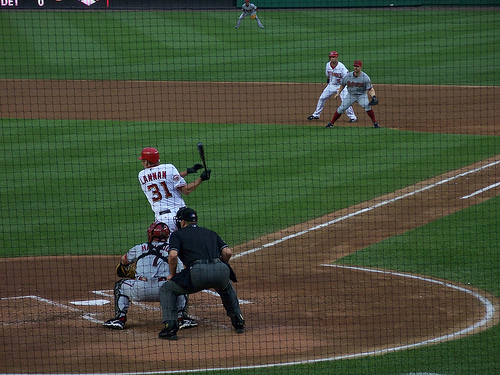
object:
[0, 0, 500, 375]
net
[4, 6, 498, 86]
grass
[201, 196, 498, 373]
grass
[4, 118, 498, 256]
grass